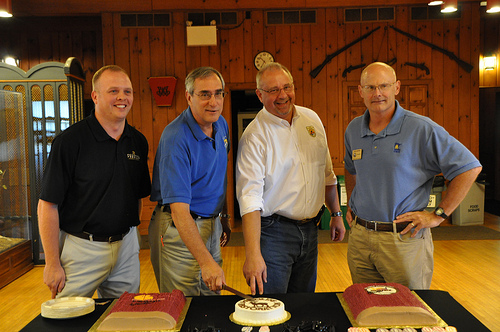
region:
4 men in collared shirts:
[34, 61, 486, 294]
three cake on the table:
[91, 284, 457, 330]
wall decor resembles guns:
[306, 35, 473, 84]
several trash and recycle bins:
[316, 165, 492, 237]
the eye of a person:
[107, 86, 121, 96]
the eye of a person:
[125, 87, 140, 106]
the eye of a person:
[213, 92, 223, 102]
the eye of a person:
[270, 84, 277, 96]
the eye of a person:
[286, 82, 291, 89]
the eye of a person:
[366, 80, 377, 93]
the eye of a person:
[381, 83, 390, 97]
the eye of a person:
[122, 87, 142, 99]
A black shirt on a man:
[37, 115, 149, 236]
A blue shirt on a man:
[143, 106, 233, 216]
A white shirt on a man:
[238, 106, 336, 219]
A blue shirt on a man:
[327, 103, 482, 217]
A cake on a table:
[230, 293, 287, 323]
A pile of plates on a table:
[33, 295, 97, 317]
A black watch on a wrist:
[430, 205, 445, 219]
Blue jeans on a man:
[259, 215, 322, 292]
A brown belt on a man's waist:
[347, 212, 408, 232]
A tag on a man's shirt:
[350, 145, 363, 161]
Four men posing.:
[29, 63, 483, 295]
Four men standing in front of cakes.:
[17, 62, 489, 330]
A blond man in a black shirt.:
[34, 64, 153, 299]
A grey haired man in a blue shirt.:
[150, 63, 229, 296]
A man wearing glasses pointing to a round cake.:
[232, 63, 347, 330]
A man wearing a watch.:
[338, 60, 483, 289]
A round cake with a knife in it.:
[221, 282, 292, 324]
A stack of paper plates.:
[38, 295, 97, 316]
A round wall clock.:
[253, 48, 275, 75]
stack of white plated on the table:
[42, 294, 95, 318]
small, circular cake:
[233, 295, 286, 326]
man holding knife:
[148, 65, 233, 292]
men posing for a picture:
[38, 61, 480, 293]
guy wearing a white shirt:
[234, 63, 345, 292]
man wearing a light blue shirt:
[343, 62, 480, 288]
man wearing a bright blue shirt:
[145, 66, 247, 292]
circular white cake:
[232, 295, 285, 322]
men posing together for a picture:
[38, 63, 482, 296]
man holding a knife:
[147, 66, 233, 290]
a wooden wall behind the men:
[16, 12, 484, 221]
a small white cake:
[232, 295, 285, 323]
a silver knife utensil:
[218, 284, 256, 302]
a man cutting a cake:
[146, 66, 287, 325]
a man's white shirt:
[236, 104, 338, 224]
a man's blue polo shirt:
[151, 102, 230, 214]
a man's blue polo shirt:
[342, 103, 482, 223]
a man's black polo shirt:
[39, 112, 153, 239]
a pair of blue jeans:
[253, 217, 318, 293]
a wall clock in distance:
[252, 50, 274, 71]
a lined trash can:
[452, 173, 487, 225]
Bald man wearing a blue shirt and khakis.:
[340, 61, 480, 286]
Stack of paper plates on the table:
[41, 286, 96, 321]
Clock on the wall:
[252, 45, 273, 68]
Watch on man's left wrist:
[433, 200, 446, 222]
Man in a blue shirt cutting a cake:
[151, 61, 291, 326]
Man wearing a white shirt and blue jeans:
[235, 55, 346, 300]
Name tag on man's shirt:
[348, 143, 363, 159]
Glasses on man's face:
[195, 82, 226, 98]